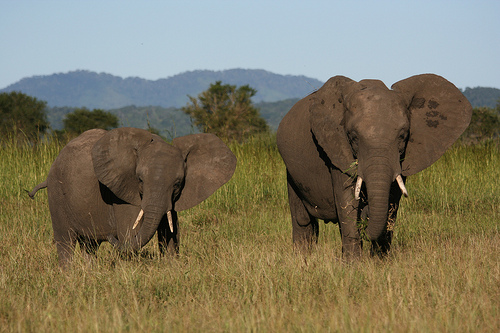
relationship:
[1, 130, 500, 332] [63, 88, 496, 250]
grass around elephants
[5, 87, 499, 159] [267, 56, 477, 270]
trees behind elephant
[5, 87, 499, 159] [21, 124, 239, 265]
trees behind elephant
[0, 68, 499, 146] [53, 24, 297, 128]
hill in background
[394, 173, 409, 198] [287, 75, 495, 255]
tusk on elephant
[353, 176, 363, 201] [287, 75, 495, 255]
tusk on elephant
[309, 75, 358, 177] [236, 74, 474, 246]
ear belonging to elephant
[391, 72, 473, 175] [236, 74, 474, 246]
ear belonging to elephant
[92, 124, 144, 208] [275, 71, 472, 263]
ear belonging to elephant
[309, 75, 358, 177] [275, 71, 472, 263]
ear belonging to elephant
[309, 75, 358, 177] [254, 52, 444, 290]
ear belonging to elephant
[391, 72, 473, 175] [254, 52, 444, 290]
ear belonging to elephant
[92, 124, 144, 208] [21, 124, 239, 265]
ear belonging to elephant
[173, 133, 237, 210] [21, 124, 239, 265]
ear belonging to elephant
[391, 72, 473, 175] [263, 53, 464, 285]
ear belonging to elephant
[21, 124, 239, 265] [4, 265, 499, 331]
elephant standing in grass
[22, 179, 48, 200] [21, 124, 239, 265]
tail belonging to elephant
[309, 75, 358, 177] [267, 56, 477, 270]
ear belonging to elephant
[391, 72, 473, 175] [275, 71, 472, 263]
ear belonging to elephant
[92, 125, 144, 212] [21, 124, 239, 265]
ear belonging to elephant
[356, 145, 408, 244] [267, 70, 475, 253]
trunk belonging to elephant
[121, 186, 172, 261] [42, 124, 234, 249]
trunk belonging to elephant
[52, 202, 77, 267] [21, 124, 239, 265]
leg belonging to elephant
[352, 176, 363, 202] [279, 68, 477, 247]
tusk belonging to elephant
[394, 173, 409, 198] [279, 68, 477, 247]
tusk belonging to elephant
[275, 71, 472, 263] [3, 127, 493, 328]
elephant standing in grasslands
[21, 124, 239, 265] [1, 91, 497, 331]
elephant standing in grasslands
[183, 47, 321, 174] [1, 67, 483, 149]
tree standing in background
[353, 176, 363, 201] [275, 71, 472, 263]
tusk belonging to elephant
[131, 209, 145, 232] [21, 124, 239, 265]
tusk belonging to elephant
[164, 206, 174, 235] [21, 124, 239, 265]
tusk belonging to elephant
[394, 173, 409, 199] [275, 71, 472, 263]
tusk belonging to elephant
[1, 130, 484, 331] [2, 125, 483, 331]
grass growing in field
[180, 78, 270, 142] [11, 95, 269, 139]
tree in forest